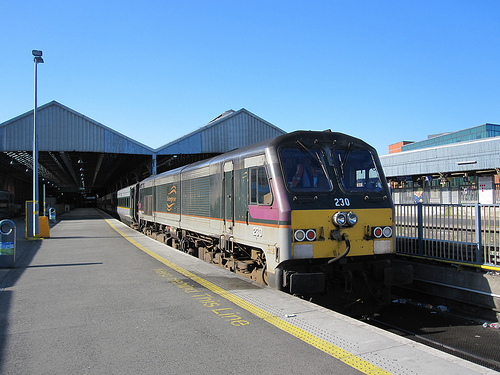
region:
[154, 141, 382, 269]
black and yellow train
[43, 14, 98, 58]
white clouds in blue sky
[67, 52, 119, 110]
white clouds in blue sky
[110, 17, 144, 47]
white clouds in blue sky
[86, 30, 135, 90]
white clouds in blue sky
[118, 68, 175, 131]
white clouds in blue sky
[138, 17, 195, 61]
white clouds in blue sky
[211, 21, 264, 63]
white clouds in blue sky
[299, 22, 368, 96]
white clouds in blue sky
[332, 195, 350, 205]
The train number is 230.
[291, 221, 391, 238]
Two lights are on each side of the train.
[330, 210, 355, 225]
Two lights are in the center of the train.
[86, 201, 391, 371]
A yellow line runs along the platform.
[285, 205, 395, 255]
The lower front of the train is yellow.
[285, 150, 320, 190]
A train worker is inside the train.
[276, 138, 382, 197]
The front windows have windshield wipers.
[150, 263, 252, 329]
The words are in yellow paint.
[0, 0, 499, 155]
The sky is blue and clear.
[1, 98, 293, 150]
The train station has two points.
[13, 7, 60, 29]
white clouds in blue sky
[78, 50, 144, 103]
white clouds in blue sky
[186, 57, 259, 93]
white clouds in blue sky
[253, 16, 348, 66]
white clouds in blue sky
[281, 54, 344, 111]
white clouds in blue sky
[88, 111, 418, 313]
a train on a railroad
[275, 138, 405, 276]
front of train is yellow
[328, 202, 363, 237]
headlights of train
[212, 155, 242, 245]
door of train is silver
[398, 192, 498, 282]
rail on side the railroad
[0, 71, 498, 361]
train in a train station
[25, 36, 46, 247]
pole with two lights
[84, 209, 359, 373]
a yellow line on platform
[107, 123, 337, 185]
roof of train is color silver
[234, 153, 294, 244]
pink color on side the train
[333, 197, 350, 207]
number of train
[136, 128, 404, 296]
yellow black and grey train engine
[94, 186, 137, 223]
several train cars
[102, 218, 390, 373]
yellow caution line on platform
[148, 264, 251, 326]
"keep behind this line" written in yellow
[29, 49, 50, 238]
metal light post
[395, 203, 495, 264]
fence beside train tracks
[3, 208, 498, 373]
platform at train station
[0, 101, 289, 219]
metal cover over train station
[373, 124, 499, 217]
structure at train station